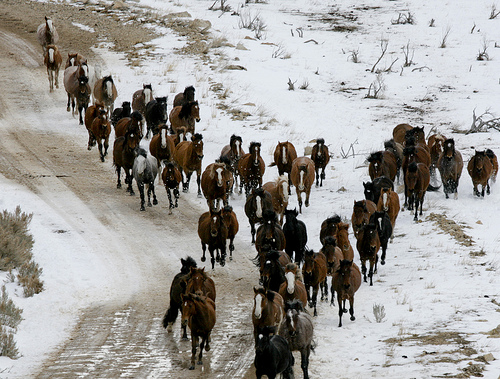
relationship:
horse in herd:
[332, 258, 364, 329] [32, 15, 495, 377]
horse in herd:
[32, 8, 62, 58] [32, 15, 495, 377]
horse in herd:
[289, 153, 316, 213] [32, 15, 495, 377]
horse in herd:
[465, 145, 490, 199] [32, 15, 495, 377]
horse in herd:
[149, 124, 176, 161] [32, 15, 495, 377]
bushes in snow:
[0, 202, 48, 360] [4, 5, 498, 377]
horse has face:
[252, 322, 296, 377] [251, 325, 272, 356]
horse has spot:
[252, 322, 296, 377] [256, 330, 263, 340]